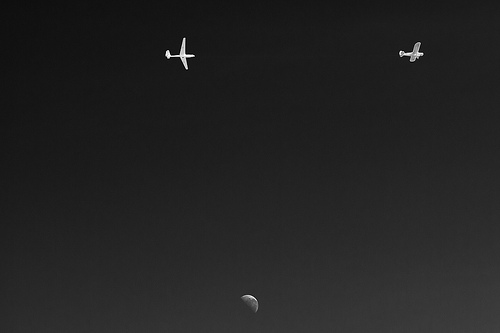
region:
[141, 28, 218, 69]
white plane in the sky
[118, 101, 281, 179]
black skies in the night sky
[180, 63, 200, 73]
wing on white plane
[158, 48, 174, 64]
tail on the plane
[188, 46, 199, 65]
small front of the plane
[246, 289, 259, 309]
shadow on the moon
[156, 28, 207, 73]
white plane in sky on left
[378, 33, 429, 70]
white plane in sky on right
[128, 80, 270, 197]
dark black nighttime sky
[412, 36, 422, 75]
rounded wings of plane on right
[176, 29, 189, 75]
pointed wings of plane on left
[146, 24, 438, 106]
two planes in nighttime sky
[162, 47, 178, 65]
tail of plane on left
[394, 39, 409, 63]
tail of plane on right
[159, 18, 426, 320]
two planes and the moon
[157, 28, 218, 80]
an airplane in the sky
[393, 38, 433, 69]
a plane in the sky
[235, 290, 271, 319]
a moon in the sky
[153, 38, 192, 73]
a white airplane in the sky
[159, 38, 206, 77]
a white plane in the sky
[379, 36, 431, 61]
a white airplane in the sky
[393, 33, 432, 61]
a white plane in the sky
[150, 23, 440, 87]
two planes in the sky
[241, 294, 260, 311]
The grey colored moon.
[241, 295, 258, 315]
A half a moon.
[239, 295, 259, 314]
Dark moon in the sky.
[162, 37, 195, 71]
Larger white plane in the sky with long wings.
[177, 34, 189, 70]
Long white wings on a bigger plane.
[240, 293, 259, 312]
Mostly grey half moon.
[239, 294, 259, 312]
Part of a moon.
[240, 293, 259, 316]
Grey moon in the dark.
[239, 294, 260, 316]
A moon that is grey.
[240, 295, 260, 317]
Half of a moon in a dark sky.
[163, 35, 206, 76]
white plane in black sky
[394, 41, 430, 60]
white plane in black sky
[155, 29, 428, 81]
two white planes in black sky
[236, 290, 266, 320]
grey moon in black sky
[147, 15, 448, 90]
two planes flying over moon in night sky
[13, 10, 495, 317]
black and white image of two planes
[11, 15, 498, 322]
outer space surreal photo of planes over moon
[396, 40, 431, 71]
white plane flying at angle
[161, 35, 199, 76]
white plane flying stright in night sky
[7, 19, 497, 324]
black sky with moon and planes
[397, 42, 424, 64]
an airplane in the sky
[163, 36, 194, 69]
an airplane in the sky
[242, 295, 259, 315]
a half moon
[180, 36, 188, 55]
a wing on a plane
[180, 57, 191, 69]
a wing on a plane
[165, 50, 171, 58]
a tail wing on a plane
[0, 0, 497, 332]
a dark night sky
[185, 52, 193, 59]
a nose on an airplane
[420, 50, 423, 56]
the nose on an airplane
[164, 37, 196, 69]
white glider with large wingspan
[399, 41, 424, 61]
a white prop plane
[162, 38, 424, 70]
white prop plane pulling white glider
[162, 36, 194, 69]
rotorless airplane flying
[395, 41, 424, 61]
white plane making a turn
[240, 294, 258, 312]
moon floating in the sky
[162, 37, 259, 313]
white glider flying by the moon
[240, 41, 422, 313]
white plane flying by the moon